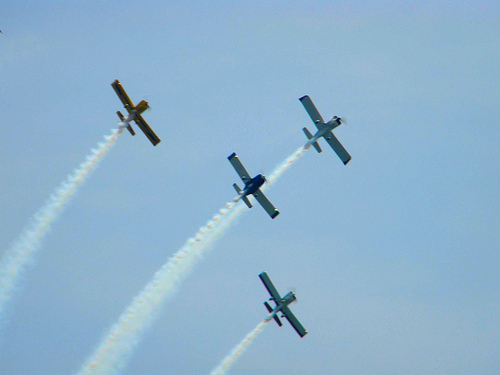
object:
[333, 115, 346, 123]
propellars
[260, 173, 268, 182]
propellars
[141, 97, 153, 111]
propellars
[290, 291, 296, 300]
propellars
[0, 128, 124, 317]
cloud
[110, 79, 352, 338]
squadron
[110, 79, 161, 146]
airplane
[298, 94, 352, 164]
airplane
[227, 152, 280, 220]
airplane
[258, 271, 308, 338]
airplane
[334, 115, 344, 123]
propeller engine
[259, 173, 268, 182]
propeller engine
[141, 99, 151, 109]
propeller engine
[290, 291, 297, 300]
propeller engine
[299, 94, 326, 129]
wing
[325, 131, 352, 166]
wing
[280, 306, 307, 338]
wing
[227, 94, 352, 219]
two choppers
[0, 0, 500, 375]
sky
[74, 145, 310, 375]
cloud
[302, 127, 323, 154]
fin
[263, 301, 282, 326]
fin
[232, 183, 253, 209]
fin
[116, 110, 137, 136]
fin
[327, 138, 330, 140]
wheels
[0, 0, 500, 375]
air